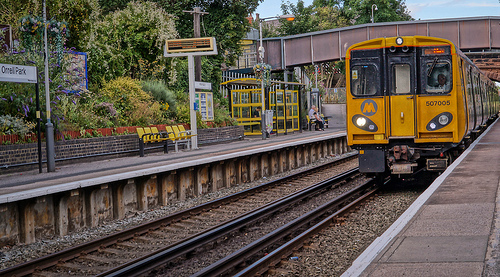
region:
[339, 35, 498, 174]
yellow train on track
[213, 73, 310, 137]
yellow waiting area by train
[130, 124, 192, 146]
yellow benches by tracks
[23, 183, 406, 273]
train tracks with gravel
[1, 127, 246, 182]
brick wall by bench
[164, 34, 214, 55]
yellow bordered sign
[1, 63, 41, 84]
white sign with writing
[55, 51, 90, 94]
white and blue bordered sign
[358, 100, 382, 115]
yellow m on train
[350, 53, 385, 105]
window of a train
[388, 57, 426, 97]
window of a train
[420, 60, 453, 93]
window of a train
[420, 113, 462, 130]
light of a train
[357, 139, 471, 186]
front of a train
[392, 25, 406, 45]
light of a train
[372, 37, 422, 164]
door of a train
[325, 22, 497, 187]
a long yellow train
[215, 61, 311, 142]
a yellow and black shelter for train patrons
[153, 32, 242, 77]
a yellow and black sign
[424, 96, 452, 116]
black numbers on front of train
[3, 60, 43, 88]
a white sign with black letters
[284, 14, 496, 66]
a bridge above the train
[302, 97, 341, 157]
a gray shirt and black pants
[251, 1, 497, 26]
blue of daytime sky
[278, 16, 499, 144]
walkway over train tracks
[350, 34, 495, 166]
passenger train next to platform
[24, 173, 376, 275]
rails of train tracks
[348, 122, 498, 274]
white line on edge of platform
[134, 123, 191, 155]
yellow seats facing tracks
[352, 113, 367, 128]
glowing round train light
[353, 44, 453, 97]
windows on front of train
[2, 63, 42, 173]
sign on black pole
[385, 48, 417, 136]
yellow door on train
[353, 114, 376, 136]
head light on train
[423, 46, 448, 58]
destination sign on train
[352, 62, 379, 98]
front window on train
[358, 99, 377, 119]
grey decal on train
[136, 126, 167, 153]
yellow chairs on sidewalk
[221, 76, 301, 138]
yellow train stop building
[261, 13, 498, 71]
grey stone walking bridge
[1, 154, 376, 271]
metal and wood train tracks